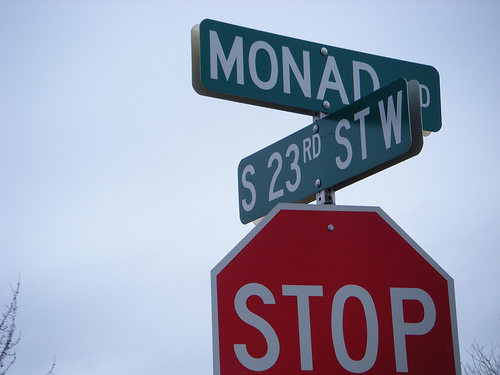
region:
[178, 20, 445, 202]
Two green signs above the stop sign.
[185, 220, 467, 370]
A stop sign on the pole.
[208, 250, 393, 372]
The stop sign is red.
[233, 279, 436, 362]
The letters on the sign is white.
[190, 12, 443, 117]
The top green sign says Monad.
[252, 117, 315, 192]
The number on the bottom sign is 23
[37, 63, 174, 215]
The sky is clear and blue.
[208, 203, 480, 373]
The shape of the sign is an octagon.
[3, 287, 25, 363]
A branch from a tree.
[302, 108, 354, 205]
A silver pole is metal.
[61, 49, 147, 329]
sky with clouds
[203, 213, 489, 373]
octogonal shape of traffic sign board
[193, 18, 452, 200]
green color street name board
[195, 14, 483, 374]
the boards are attached in a metal post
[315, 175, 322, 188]
bolt of the metal post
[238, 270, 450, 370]
stop sign board with red and white color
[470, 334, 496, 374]
some grass near the sign board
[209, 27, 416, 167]
the streetboard written in white color text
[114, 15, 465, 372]
sky background with the board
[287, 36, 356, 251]
lot of bolts in the metal post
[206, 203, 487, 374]
this is a sign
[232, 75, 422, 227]
this is a sign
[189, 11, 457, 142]
this is a sign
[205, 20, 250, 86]
a letter on the sign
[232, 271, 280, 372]
a letter on the sign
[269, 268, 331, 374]
a letter on the sign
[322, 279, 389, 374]
a letter on the sign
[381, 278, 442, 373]
a letter on the sign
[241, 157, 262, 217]
a letter on the sign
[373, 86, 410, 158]
a letter on the sign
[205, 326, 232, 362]
edge of a board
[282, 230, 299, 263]
part of a board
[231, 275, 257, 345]
part of a letter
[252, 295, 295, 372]
part of a letter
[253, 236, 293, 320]
part of a board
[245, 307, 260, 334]
part of a letter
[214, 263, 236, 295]
edge of a board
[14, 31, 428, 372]
picture taken outside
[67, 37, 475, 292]
picture taken during the day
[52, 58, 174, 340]
a very cloudy day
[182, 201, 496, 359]
a red and white stop sign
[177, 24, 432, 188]
two street signs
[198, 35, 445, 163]
the street signs are green and white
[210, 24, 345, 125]
a street sign says MONAD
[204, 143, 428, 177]
a street sign says S 23rd ST W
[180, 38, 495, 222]
the signs are perpendicular to each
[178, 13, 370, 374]
the signs are on top of each other